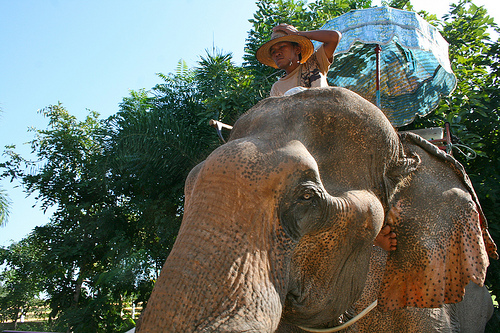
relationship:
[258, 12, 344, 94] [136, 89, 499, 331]
man riding elephant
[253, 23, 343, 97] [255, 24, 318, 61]
man wearing hat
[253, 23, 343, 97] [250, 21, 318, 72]
man holding hat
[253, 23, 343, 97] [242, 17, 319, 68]
man holding hat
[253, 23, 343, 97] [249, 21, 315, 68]
man holding hat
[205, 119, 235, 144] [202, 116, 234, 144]
ax tool resembling ax tool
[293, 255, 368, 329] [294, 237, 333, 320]
skin under chin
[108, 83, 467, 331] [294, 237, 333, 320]
elephant has chin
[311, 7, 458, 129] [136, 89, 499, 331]
blue umbrella on back of elephant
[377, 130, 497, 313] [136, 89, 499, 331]
ear of elephant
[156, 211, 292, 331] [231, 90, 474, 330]
trunk of elephant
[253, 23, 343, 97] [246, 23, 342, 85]
man holding hat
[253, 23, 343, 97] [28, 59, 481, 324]
man on an elephant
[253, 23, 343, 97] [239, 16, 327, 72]
man holding hat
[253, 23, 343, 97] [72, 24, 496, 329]
man on an elephant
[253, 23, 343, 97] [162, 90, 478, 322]
man riding elephant